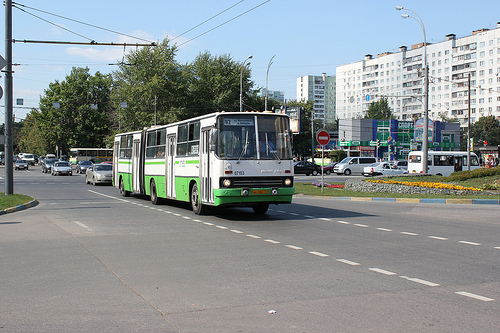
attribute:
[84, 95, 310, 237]
bus — green, white, moving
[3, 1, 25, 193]
post — tall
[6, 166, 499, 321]
road — grey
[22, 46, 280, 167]
trees — green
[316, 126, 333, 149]
sign — red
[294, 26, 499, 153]
building — big, white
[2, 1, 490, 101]
sky — blue, big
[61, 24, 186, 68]
clouds — small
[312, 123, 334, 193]
sign — red, white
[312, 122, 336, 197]
sign — do not enter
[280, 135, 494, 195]
lot — parking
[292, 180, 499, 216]
curb — yellow, blue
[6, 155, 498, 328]
street — busy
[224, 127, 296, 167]
wipers — windshield